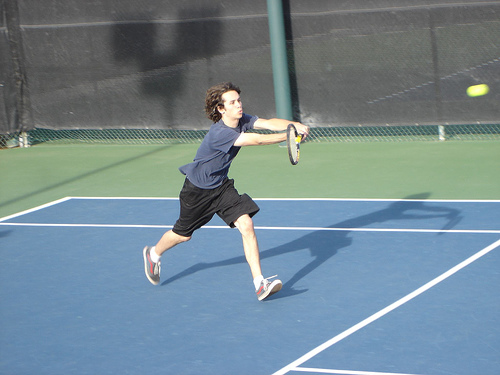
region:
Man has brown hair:
[195, 79, 240, 121]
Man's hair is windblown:
[201, 74, 249, 131]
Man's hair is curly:
[195, 70, 232, 116]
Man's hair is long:
[197, 72, 237, 122]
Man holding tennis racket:
[276, 110, 321, 175]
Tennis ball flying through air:
[420, 65, 490, 101]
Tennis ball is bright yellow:
[455, 71, 490, 102]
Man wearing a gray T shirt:
[185, 115, 245, 190]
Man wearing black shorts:
[170, 160, 265, 230]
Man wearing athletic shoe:
[245, 268, 293, 303]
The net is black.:
[325, 18, 430, 105]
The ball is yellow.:
[460, 70, 488, 102]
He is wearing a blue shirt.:
[182, 104, 325, 249]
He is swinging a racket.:
[143, 73, 329, 352]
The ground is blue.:
[73, 284, 244, 374]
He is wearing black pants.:
[118, 81, 290, 305]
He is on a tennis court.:
[7, 30, 464, 369]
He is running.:
[128, 62, 318, 315]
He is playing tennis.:
[140, 81, 346, 325]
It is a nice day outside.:
[18, 14, 463, 369]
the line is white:
[349, 291, 374, 331]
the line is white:
[331, 336, 341, 351]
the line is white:
[325, 336, 334, 360]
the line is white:
[329, 346, 341, 357]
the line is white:
[335, 337, 347, 348]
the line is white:
[284, 361, 296, 374]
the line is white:
[294, 355, 301, 374]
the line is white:
[291, 332, 303, 372]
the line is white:
[286, 360, 290, 369]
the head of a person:
[200, 72, 249, 127]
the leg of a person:
[218, 182, 265, 285]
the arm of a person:
[215, 125, 286, 162]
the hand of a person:
[290, 115, 318, 138]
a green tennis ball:
[463, 77, 491, 102]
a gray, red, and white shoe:
[141, 241, 168, 288]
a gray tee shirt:
[173, 109, 260, 191]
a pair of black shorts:
[169, 172, 262, 241]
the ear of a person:
[212, 100, 229, 117]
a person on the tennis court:
[137, 72, 313, 302]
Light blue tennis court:
[4, 184, 490, 371]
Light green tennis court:
[1, 131, 494, 236]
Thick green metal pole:
[236, 0, 293, 147]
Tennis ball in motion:
[453, 72, 498, 114]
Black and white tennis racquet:
[272, 116, 322, 177]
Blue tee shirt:
[174, 93, 276, 210]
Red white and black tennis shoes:
[125, 236, 310, 315]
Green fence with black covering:
[42, 0, 497, 135]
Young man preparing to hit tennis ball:
[99, 28, 330, 313]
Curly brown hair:
[185, 71, 246, 128]